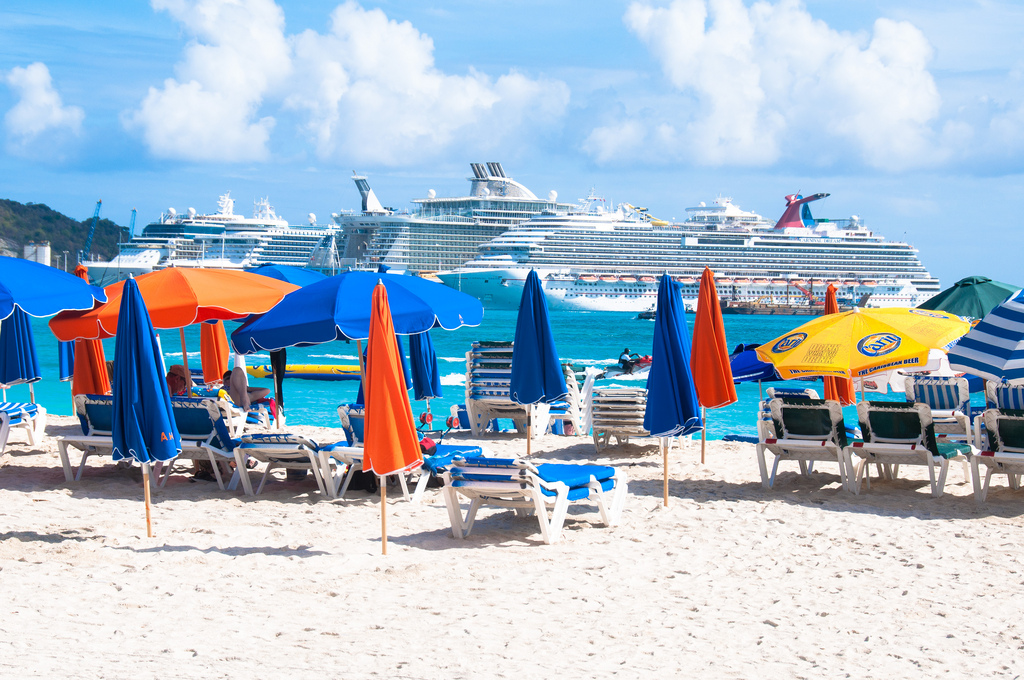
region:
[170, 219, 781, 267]
Cruise boats achored in a harbor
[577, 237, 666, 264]
The different decks on a cruise boat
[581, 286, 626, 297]
Windows on the lower deck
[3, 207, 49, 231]
Vegetation on the side of a hill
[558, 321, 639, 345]
Blue turquoise water near the beach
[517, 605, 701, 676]
Surface of sand on the beach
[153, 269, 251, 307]
The outer surfacd of an open orange umbrella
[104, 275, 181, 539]
closed blue umbrella in the sand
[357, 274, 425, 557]
closed orange umbrella in the sand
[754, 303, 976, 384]
open yellow umbrella with blue logos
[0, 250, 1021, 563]
umbrellas and lounge chairs on the beach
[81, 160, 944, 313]
cruise ships in the water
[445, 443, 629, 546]
blue and white lounge chairs stacked together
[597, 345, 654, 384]
person on a jet ski in the water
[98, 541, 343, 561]
shadow on the sand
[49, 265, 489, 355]
open orange umbrella next to open blue umbrella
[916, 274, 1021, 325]
green umbrella behind the yellow umbrella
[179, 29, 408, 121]
Large body of skies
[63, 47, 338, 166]
Large body of skies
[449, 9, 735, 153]
Large body of skies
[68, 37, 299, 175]
Large body of skies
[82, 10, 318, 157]
Large body of skies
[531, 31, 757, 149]
Large body of skies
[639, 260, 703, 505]
Blue umbrella stuck in sand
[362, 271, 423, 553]
Orange umbrella stuck in sand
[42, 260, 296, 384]
Orange umbrella next to a blue umbrella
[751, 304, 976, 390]
Yellow umbrella in front of a chair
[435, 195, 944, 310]
Large cruise on the water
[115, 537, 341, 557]
Shadow of umbrella on the sand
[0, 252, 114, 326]
Blue umbrella next to an orange umbrella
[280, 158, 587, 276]
Large cruise ship next to another cruise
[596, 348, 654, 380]
Jet ski on the water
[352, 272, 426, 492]
red colored umbrella in sand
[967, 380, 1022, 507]
A chair that is outside.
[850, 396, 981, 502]
A chair that is outside.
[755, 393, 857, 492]
A chair that is outside.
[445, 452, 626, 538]
A chair that is outside.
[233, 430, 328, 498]
A chair that is outside.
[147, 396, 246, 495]
A chair that is outside.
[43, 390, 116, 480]
A chair that is outside.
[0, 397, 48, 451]
A chair that is outside.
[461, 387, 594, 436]
A chair that is outside.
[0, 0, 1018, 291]
a blue sky full of clouds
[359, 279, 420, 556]
an orange umbrella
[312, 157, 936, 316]
a large white ship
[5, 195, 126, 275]
a small green hill in the background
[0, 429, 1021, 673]
white colored sand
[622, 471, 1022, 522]
shadow on the sand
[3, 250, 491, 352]
three open umbrellas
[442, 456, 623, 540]
lounge chairs with blue cushions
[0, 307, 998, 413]
bright blue water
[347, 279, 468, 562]
A large open umbrella.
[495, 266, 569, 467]
A large open umbrella.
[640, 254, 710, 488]
A large open umbrella.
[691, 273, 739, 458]
A large open umbrella.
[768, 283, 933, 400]
A large open umbrella.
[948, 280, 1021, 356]
A large open umbrella.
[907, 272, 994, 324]
A large open umbrella.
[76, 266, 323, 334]
A large open umbrella.